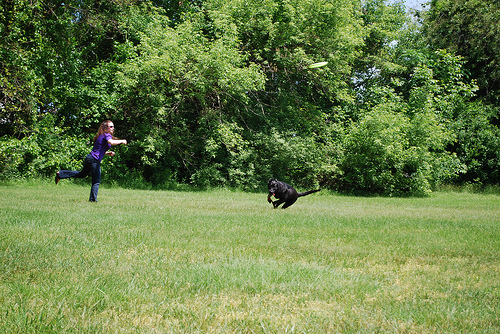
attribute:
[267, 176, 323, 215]
dog — black, running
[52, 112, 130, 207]
girl — standing, playing, white, running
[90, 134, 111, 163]
shirt — purple, casual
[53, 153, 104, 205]
jeans — blue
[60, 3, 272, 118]
tree — green, dense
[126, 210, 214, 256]
grass — green, a patch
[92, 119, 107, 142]
hair — long, red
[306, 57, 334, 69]
frisbee — green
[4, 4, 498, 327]
field — grassy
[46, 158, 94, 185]
leg — up, bent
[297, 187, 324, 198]
tail — black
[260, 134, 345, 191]
bush — green